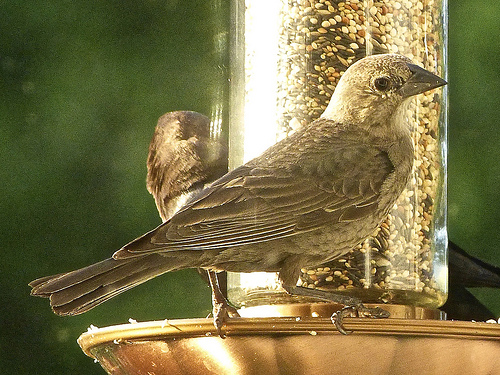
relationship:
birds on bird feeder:
[109, 85, 365, 325] [271, 39, 327, 87]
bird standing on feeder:
[26, 51, 449, 338] [75, 1, 498, 372]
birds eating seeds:
[145, 110, 238, 341] [280, 0, 444, 304]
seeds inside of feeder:
[280, 0, 444, 304] [75, 1, 498, 372]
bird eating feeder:
[26, 51, 449, 338] [75, 1, 498, 372]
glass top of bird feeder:
[224, 0, 449, 305] [75, 0, 498, 373]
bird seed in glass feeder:
[279, 0, 444, 302] [224, 0, 449, 309]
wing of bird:
[110, 122, 389, 258] [26, 51, 449, 338]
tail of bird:
[22, 255, 184, 317] [26, 51, 449, 338]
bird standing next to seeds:
[26, 51, 449, 338] [280, 0, 444, 304]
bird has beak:
[26, 51, 449, 338] [398, 63, 449, 99]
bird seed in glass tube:
[279, 0, 444, 302] [222, 0, 447, 305]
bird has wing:
[26, 51, 449, 338] [104, 138, 403, 268]